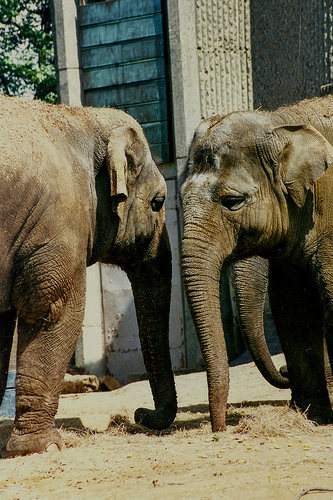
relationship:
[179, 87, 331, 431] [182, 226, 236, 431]
elephant has trunk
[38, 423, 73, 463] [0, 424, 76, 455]
toe on foot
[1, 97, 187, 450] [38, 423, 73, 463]
elephant has toe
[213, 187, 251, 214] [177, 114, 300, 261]
eye in head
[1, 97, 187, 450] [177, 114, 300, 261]
elephant has head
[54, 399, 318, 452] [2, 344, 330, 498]
hay on ground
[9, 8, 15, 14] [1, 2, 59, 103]
leaves on tree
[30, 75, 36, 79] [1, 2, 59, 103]
leaves on tree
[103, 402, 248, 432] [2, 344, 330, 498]
shadow on ground